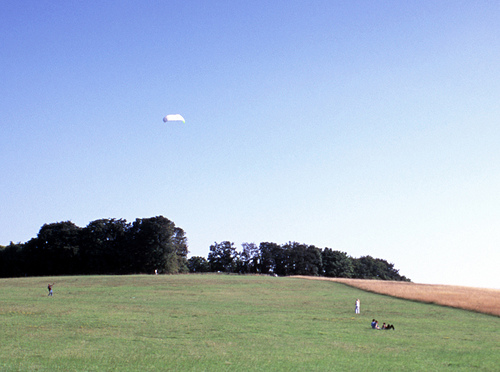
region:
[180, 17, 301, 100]
blue sky above land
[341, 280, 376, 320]
person on the grass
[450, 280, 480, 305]
brown dirt next to people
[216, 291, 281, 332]
green grass below the people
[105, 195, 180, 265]
trees in the distance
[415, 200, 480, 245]
light part of sky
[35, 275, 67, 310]
person standing in grass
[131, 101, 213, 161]
object in the air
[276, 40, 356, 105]
sky with no clouds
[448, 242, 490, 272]
bright part of sky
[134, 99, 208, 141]
a white object in air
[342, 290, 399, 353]
group of people sitting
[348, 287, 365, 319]
a white person standing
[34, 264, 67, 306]
a person standing in grass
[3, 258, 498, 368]
a beautiful view of grass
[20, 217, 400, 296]
a group of trees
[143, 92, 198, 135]
a white parachute in air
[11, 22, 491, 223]
a beautiful view of sky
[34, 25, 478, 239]
a nice view of sky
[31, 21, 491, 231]
white sky with no clouds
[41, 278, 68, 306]
person standing in a field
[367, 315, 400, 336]
people sitting in a field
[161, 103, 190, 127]
kite flying in the air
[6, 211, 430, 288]
row of dark green trees on the edge of the field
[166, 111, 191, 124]
bright white streak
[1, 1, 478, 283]
clear sky with no cliuds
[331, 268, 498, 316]
patch of brown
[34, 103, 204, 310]
person flying a kite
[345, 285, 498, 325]
black line separating the green from the brown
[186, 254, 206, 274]
small green tree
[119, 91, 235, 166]
a kite in the air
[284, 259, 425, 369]
people on the field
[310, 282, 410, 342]
people on the grass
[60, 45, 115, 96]
a blue clear sky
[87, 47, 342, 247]
a kite in the air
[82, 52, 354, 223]
a kite flying in the air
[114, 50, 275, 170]
a kite flying in the sky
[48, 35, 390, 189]
a kite in the blue sky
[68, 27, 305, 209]
a kite in the blue air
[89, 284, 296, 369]
a field of green grass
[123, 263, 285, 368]
the grass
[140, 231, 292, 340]
the grass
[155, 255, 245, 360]
the grass